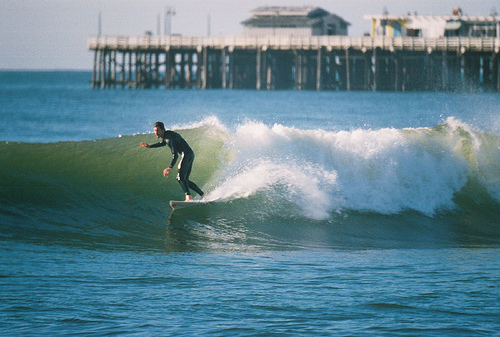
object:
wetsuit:
[147, 130, 204, 195]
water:
[209, 163, 339, 226]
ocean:
[0, 95, 499, 336]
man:
[140, 120, 208, 202]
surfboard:
[170, 199, 199, 210]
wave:
[3, 118, 499, 218]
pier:
[91, 34, 499, 95]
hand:
[141, 140, 150, 148]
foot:
[183, 195, 194, 202]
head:
[153, 121, 165, 138]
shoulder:
[165, 127, 172, 145]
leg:
[178, 154, 190, 192]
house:
[241, 5, 353, 35]